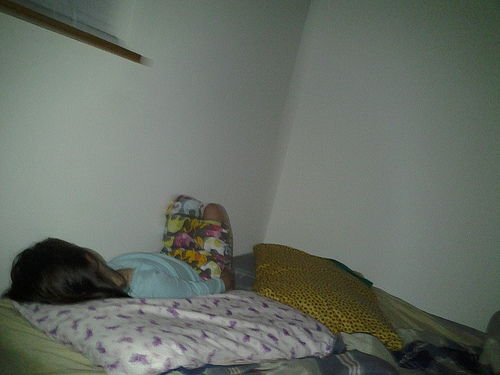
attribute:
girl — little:
[2, 192, 237, 312]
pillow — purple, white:
[10, 281, 346, 373]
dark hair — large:
[2, 234, 137, 309]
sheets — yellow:
[1, 313, 48, 367]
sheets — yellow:
[381, 287, 477, 340]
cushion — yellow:
[250, 232, 408, 358]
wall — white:
[256, 3, 496, 335]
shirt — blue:
[104, 250, 227, 302]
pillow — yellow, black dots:
[252, 241, 402, 351]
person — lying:
[2, 190, 236, 307]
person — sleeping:
[8, 194, 234, 302]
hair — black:
[4, 222, 134, 323]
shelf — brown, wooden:
[0, 7, 147, 65]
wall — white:
[4, 3, 292, 273]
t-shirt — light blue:
[100, 229, 206, 309]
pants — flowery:
[128, 201, 250, 283]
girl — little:
[6, 187, 248, 318]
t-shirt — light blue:
[104, 242, 230, 303]